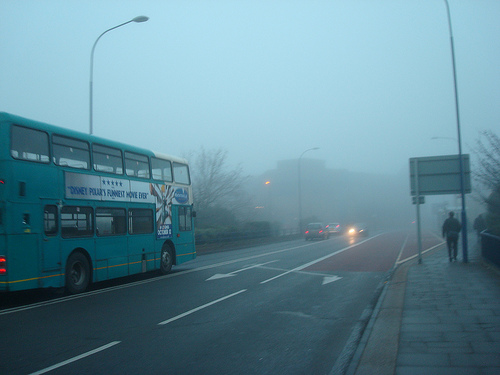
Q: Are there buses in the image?
A: Yes, there is a bus.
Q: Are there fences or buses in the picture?
A: Yes, there is a bus.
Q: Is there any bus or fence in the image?
A: Yes, there is a bus.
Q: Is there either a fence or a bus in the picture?
A: Yes, there is a bus.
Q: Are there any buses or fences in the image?
A: Yes, there is a bus.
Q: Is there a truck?
A: No, there are no trucks.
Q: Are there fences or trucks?
A: No, there are no trucks or fences.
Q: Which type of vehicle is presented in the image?
A: The vehicle is a bus.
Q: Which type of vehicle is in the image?
A: The vehicle is a bus.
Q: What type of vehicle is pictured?
A: The vehicle is a bus.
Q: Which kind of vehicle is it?
A: The vehicle is a bus.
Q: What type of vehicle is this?
A: This is a bus.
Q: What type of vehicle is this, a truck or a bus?
A: This is a bus.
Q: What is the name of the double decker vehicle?
A: The vehicle is a bus.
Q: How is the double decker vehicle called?
A: The vehicle is a bus.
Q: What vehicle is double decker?
A: The vehicle is a bus.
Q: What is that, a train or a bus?
A: That is a bus.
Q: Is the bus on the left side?
A: Yes, the bus is on the left of the image.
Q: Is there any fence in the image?
A: No, there are no fences.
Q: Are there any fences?
A: No, there are no fences.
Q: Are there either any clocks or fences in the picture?
A: No, there are no fences or clocks.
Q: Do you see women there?
A: No, there are no women.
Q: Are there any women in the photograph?
A: No, there are no women.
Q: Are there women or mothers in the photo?
A: No, there are no women or mothers.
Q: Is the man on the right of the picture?
A: Yes, the man is on the right of the image.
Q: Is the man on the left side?
A: No, the man is on the right of the image.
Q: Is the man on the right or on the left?
A: The man is on the right of the image.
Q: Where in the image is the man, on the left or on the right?
A: The man is on the right of the image.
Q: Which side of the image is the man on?
A: The man is on the right of the image.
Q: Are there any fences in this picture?
A: No, there are no fences.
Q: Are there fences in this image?
A: No, there are no fences.